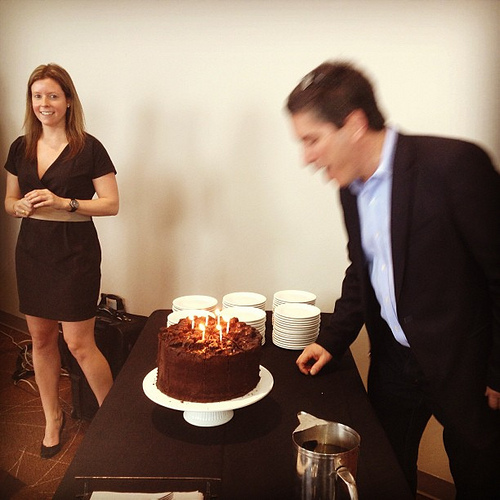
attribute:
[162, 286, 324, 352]
plate — white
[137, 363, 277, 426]
stand — White , Large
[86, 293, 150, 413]
suitcase — black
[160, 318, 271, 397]
cake — chocolate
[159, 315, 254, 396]
cake — chocolate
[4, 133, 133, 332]
dress — black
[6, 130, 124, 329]
dress — black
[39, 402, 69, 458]
pumps — black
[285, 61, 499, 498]
man — caucasian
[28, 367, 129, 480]
shoe — Small , Black 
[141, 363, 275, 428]
dish — white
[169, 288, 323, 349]
stacks — small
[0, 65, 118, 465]
woman — smiling, standing